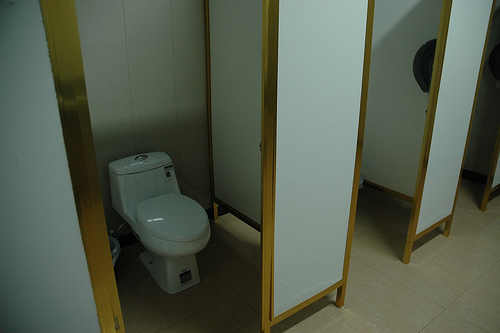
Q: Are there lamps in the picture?
A: No, there are no lamps.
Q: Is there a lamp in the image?
A: No, there are no lamps.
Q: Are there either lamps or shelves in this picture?
A: No, there are no lamps or shelves.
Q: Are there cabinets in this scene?
A: No, there are no cabinets.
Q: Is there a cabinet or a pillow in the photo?
A: No, there are no cabinets or pillows.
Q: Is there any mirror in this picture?
A: No, there are no mirrors.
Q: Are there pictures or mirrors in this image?
A: No, there are no mirrors or pictures.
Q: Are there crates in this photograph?
A: No, there are no crates.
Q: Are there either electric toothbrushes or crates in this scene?
A: No, there are no crates or electric toothbrushes.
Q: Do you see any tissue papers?
A: No, there are no tissue papers.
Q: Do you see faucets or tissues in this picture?
A: No, there are no tissues or faucets.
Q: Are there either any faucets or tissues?
A: No, there are no tissues or faucets.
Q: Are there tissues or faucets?
A: No, there are no tissues or faucets.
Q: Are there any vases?
A: No, there are no vases.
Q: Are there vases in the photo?
A: No, there are no vases.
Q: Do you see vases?
A: No, there are no vases.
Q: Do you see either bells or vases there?
A: No, there are no vases or bells.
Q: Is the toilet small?
A: Yes, the toilet is small.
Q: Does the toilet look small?
A: Yes, the toilet is small.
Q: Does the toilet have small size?
A: Yes, the toilet is small.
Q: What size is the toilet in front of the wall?
A: The toilet is small.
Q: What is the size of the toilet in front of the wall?
A: The toilet is small.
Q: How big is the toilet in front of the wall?
A: The toilet is small.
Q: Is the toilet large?
A: No, the toilet is small.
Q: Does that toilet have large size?
A: No, the toilet is small.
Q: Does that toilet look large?
A: No, the toilet is small.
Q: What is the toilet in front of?
A: The toilet is in front of the wall.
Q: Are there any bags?
A: Yes, there is a bag.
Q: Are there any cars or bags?
A: Yes, there is a bag.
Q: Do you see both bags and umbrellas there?
A: No, there is a bag but no umbrellas.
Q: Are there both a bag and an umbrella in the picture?
A: No, there is a bag but no umbrellas.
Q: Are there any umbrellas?
A: No, there are no umbrellas.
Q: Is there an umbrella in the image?
A: No, there are no umbrellas.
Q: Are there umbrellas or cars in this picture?
A: No, there are no umbrellas or cars.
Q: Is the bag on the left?
A: Yes, the bag is on the left of the image.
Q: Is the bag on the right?
A: No, the bag is on the left of the image.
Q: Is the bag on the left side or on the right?
A: The bag is on the left of the image.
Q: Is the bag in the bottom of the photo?
A: Yes, the bag is in the bottom of the image.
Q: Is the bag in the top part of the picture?
A: No, the bag is in the bottom of the image.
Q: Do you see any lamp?
A: No, there are no lamps.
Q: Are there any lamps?
A: No, there are no lamps.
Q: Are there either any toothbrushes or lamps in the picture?
A: No, there are no lamps or toothbrushes.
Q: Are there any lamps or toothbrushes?
A: No, there are no lamps or toothbrushes.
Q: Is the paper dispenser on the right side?
A: Yes, the paper dispenser is on the right of the image.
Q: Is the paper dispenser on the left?
A: No, the paper dispenser is on the right of the image.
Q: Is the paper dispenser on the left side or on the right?
A: The paper dispenser is on the right of the image.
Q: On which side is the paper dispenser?
A: The paper dispenser is on the right of the image.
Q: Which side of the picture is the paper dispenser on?
A: The paper dispenser is on the right of the image.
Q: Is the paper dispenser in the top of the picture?
A: Yes, the paper dispenser is in the top of the image.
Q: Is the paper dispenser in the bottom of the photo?
A: No, the paper dispenser is in the top of the image.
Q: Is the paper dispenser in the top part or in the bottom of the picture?
A: The paper dispenser is in the top of the image.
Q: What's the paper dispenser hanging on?
A: The paper dispenser is hanging on the wall.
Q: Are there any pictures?
A: No, there are no pictures.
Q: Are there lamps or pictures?
A: No, there are no pictures or lamps.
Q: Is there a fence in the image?
A: No, there are no fences.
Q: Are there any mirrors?
A: No, there are no mirrors.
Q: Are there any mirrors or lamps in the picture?
A: No, there are no mirrors or lamps.